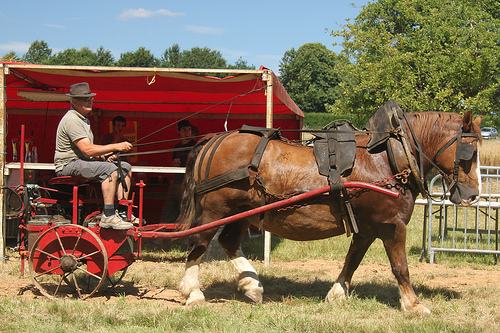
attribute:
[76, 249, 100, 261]
spoke — wooden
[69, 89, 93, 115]
head — man's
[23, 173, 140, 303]
cart — red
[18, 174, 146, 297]
cart — red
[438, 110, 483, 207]
head — horse's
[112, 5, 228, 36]
clouds — mostly clear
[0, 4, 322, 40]
sky — blue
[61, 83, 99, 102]
top hat — brown